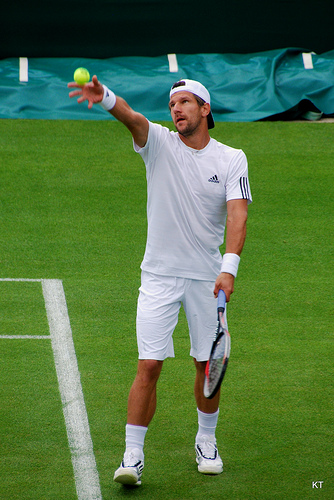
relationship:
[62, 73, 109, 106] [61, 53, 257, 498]
hand of man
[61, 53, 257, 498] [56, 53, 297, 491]
man playing tennis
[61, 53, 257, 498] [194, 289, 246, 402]
man holding tennis racket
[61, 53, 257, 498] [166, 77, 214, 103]
man wearing white hat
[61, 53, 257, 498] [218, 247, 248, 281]
man wearing wrist bands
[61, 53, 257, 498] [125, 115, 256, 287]
man wearing a shirt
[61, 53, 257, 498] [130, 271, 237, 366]
man wearing white shorts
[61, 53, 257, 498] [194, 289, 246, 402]
man holding racket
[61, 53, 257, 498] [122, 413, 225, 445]
man wearing white socks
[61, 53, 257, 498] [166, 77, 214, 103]
man wearing a hat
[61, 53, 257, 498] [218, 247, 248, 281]
man wearing bands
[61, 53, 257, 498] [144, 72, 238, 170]
man has head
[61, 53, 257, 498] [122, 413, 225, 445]
man has white sock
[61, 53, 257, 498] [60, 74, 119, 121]
man has a hand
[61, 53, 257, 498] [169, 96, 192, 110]
man has eye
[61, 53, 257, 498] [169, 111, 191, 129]
man has a mouth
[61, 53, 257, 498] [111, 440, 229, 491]
man wearing shoes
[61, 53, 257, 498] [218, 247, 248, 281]
man wearing wrist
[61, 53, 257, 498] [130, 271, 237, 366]
man dressed in tennis shorts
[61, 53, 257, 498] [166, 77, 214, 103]
man wearing cap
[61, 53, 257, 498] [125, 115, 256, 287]
man dressed white shirt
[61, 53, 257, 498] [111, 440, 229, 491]
man wearing tennis shoes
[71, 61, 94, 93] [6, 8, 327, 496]
ball in air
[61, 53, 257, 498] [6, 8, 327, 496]
man on a tennis court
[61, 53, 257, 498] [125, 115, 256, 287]
man has shirt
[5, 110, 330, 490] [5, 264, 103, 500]
grass has a white line